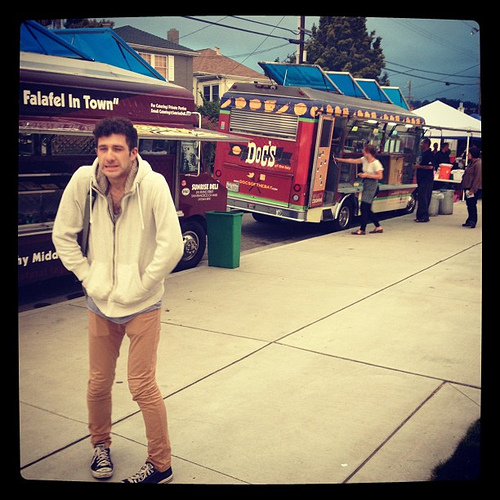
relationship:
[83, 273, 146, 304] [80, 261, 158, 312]
hands are in coat pockets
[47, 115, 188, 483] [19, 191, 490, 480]
man on sidewalk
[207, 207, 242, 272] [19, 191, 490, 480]
trash can on sidewalk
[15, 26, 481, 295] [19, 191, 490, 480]
food vendors are on sidewalk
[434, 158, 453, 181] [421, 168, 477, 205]
cooler on top of table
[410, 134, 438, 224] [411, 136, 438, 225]
man wearing black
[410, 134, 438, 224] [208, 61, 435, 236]
man standing next to food truck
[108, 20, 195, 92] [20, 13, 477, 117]
house in background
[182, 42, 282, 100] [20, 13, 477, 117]
house in background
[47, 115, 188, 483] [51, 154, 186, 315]
man wearing a sweatshirt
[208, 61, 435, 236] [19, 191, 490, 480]
food truck parked on side of sidewalk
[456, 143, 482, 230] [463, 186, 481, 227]
woman wearing pants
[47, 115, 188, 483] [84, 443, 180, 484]
man wearing sneakers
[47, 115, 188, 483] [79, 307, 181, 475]
man wearing pants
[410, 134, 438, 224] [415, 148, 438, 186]
man wearing a shirt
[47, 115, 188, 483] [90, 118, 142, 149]
man has hair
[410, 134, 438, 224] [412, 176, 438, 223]
man wearing pants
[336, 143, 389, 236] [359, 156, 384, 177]
woman wearing a shirt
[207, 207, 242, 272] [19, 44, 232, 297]
trash can next to a truck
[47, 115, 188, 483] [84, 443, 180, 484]
man wearing shoes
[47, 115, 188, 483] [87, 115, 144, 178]
man has a head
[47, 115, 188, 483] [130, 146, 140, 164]
man has an ear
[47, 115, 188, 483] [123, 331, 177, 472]
man has a leg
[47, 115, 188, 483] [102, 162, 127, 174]
man has a mouth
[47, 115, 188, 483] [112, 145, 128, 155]
man has an eye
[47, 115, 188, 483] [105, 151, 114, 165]
man has a nose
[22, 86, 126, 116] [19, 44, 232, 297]
writing on side of truck